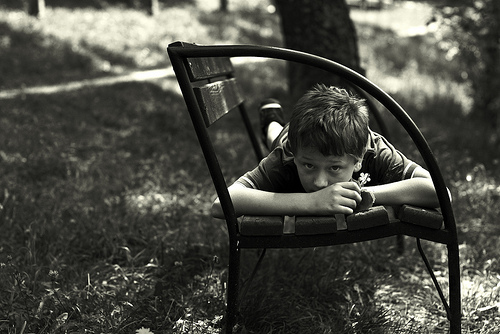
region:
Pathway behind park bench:
[0, 41, 285, 98]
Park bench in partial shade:
[165, 41, 462, 332]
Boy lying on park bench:
[213, 85, 450, 217]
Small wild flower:
[358, 171, 370, 190]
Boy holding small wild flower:
[286, 83, 371, 214]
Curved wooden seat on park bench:
[232, 201, 443, 244]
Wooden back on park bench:
[182, 50, 242, 125]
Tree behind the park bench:
[266, 0, 394, 140]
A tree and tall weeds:
[413, 0, 499, 114]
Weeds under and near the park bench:
[0, 94, 499, 331]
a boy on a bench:
[141, 29, 483, 332]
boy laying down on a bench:
[198, 50, 451, 254]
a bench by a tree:
[161, 17, 462, 319]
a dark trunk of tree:
[259, 7, 428, 227]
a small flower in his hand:
[327, 164, 383, 229]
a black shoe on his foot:
[256, 89, 298, 144]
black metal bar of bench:
[162, 33, 467, 328]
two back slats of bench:
[172, 34, 259, 129]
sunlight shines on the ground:
[128, 157, 475, 328]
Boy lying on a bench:
[208, 80, 453, 219]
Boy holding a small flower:
[208, 81, 456, 227]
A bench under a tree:
[162, 36, 467, 327]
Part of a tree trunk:
[261, 0, 363, 116]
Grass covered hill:
[3, 17, 494, 324]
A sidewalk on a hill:
[2, 40, 282, 101]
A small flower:
[355, 170, 373, 188]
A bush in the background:
[422, 1, 497, 133]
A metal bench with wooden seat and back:
[163, 36, 463, 327]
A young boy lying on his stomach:
[206, 81, 455, 231]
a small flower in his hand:
[314, 160, 399, 207]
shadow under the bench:
[174, 190, 426, 332]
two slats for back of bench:
[170, 30, 259, 125]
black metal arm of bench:
[162, 34, 477, 331]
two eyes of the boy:
[288, 153, 352, 180]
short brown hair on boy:
[272, 82, 369, 172]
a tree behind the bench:
[249, 4, 410, 157]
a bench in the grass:
[121, 12, 481, 329]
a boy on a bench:
[185, 64, 434, 293]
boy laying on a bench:
[173, 48, 446, 211]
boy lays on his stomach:
[226, 86, 436, 217]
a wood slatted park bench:
[166, 41, 471, 328]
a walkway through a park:
[0, 11, 277, 103]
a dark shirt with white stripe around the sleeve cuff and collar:
[239, 128, 414, 193]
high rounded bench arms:
[171, 39, 466, 331]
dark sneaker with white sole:
[263, 93, 280, 133]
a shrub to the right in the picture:
[424, 7, 499, 142]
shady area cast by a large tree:
[2, 15, 221, 333]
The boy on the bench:
[229, 75, 439, 241]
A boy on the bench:
[221, 80, 462, 244]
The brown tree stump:
[255, 2, 377, 113]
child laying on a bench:
[167, 35, 462, 332]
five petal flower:
[357, 171, 371, 186]